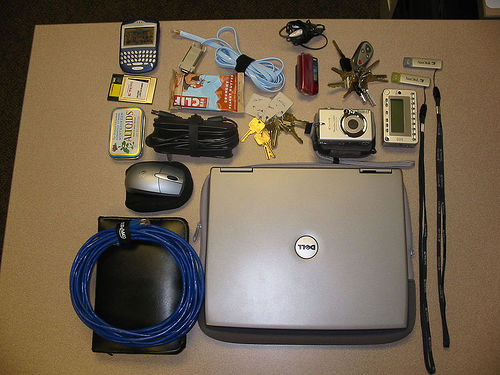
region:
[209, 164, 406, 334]
Big square shaped laptop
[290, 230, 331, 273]
A DELL Company laptop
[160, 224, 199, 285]
Blue colored wire roll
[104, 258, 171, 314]
Leather covered black book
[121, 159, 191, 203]
Small grey colored computer mouse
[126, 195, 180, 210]
Wide black colored mouse pad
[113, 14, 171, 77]
A wide analogue phone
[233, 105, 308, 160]
A bunch of keys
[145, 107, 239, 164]
Black mass of wires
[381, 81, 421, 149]
A small white gadget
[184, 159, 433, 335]
Dell laptop on a table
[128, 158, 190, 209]
Mouse on a table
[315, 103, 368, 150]
Camera on a table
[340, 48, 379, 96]
Keys on a table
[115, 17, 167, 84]
Blackberry on a table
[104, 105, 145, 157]
Altoids on a table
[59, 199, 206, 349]
Cable for a computer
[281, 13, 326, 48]
headphones on the table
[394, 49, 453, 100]
Two storage devices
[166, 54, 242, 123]
Potato chips on a table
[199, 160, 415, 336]
Silver dell laptop case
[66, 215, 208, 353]
Blue cable rolled up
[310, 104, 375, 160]
Black and silver camera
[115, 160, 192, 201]
Black and gray computer mouse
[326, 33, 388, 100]
Set of keys with key remote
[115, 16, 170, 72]
Blue and silver calculator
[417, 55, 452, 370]
Portable memory sticks on lanyards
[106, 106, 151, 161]
Canister of altoids mints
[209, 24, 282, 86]
Rolled up blue flat cable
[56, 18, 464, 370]
Various electronics and accessories on a table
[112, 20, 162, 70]
cell phone on table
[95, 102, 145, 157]
mints on a table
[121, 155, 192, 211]
mouse on a table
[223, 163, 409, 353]
lap top on a table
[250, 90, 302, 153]
keys on a table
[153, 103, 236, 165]
cord on a table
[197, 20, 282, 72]
cord on a table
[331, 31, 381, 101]
keys on a table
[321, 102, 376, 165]
camera on a table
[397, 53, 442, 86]
flash drive on a table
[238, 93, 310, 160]
a gold set of keys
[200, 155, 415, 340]
a Dell silver laptop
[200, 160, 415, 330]
a closed silver laptop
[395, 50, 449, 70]
a silver and gray flash drive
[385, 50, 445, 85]
two silver flash drives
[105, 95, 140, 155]
a can of Altoids candy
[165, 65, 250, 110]
a Clif energy bar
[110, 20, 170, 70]
a blue blackberry cellphone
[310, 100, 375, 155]
a silver camera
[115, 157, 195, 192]
a wireless mouse